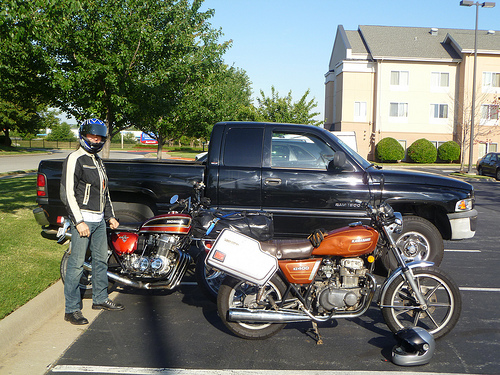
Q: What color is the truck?
A: Black.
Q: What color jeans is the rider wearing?
A: Blue.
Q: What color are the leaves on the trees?
A: Green.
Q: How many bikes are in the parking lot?
A: Two.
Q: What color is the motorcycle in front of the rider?
A: Orange.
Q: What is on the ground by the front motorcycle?
A: A helmet.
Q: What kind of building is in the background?
A: Apartments.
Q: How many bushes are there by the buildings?
A: Three.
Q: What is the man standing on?
A: Concrete.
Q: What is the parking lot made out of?
A: Asphalt.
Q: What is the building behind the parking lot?
A: An apartment building.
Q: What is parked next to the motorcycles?
A: A truck.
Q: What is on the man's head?
A: A motorcycle helmet.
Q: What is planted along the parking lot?
A: Trees.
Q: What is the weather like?
A: Sunny.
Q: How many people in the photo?
A: One.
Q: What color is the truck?
A: Black.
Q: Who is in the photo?
A: A man.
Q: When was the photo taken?
A: Day time.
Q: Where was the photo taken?
A: In a parking lot.